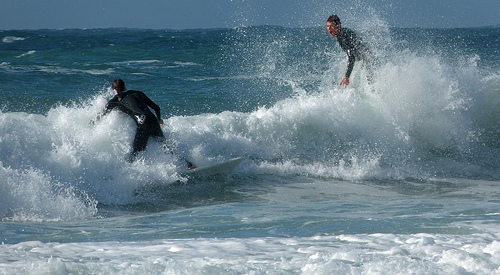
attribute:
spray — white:
[2, 0, 499, 221]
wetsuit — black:
[313, 13, 412, 83]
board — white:
[186, 153, 244, 178]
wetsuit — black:
[117, 96, 170, 145]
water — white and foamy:
[0, 192, 498, 273]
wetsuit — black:
[108, 91, 174, 150]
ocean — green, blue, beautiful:
[177, 33, 213, 103]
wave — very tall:
[268, 82, 495, 169]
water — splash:
[36, 95, 101, 140]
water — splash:
[287, 86, 346, 124]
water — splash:
[394, 46, 491, 123]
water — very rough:
[0, 1, 497, 273]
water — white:
[286, 236, 392, 268]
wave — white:
[3, 52, 495, 232]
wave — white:
[22, 115, 486, 204]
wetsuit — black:
[112, 77, 171, 169]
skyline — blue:
[48, 50, 132, 129]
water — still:
[1, 43, 206, 64]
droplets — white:
[43, 145, 184, 190]